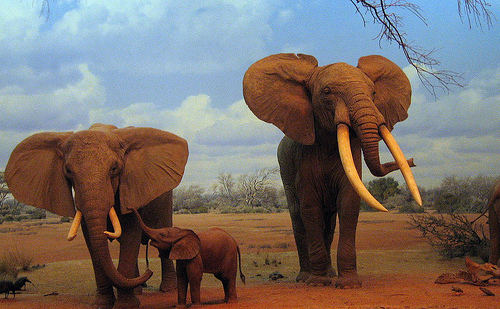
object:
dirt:
[0, 211, 499, 308]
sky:
[1, 0, 499, 197]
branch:
[413, 70, 436, 103]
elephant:
[240, 52, 426, 291]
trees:
[366, 176, 401, 212]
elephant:
[125, 204, 248, 307]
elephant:
[4, 122, 189, 307]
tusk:
[64, 206, 83, 241]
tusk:
[336, 124, 389, 216]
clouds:
[0, 0, 497, 195]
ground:
[1, 207, 499, 308]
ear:
[240, 52, 320, 146]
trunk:
[350, 109, 418, 178]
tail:
[237, 247, 247, 287]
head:
[239, 52, 415, 145]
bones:
[432, 257, 498, 285]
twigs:
[44, 289, 58, 298]